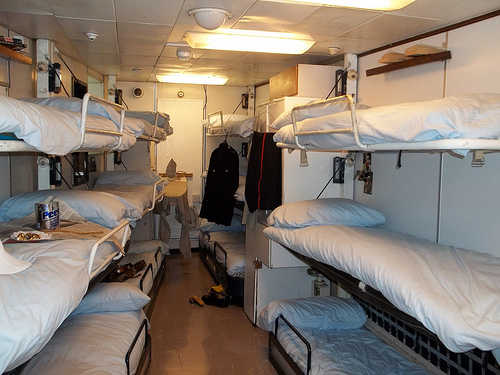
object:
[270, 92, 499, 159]
bed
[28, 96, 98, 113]
pillow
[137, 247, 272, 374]
floor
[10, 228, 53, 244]
food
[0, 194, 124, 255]
newspaper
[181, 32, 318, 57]
lighting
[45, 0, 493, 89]
ceiling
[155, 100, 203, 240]
door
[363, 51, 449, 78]
shelf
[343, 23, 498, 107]
wall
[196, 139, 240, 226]
clothes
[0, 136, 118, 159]
board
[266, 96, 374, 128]
pillowcase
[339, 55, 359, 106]
pole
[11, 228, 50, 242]
plate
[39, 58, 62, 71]
camera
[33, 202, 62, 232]
drink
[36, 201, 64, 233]
carton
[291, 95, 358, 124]
arm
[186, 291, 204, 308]
boots